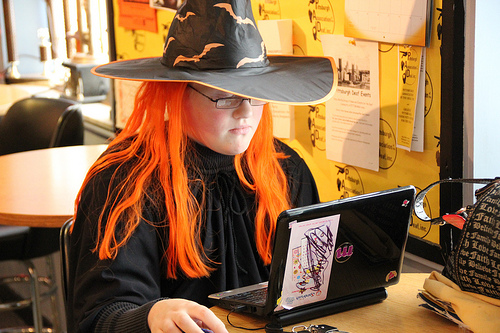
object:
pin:
[348, 40, 356, 46]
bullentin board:
[113, 0, 435, 244]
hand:
[146, 297, 234, 332]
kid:
[70, 0, 343, 333]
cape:
[85, 164, 295, 224]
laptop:
[209, 186, 424, 326]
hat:
[90, 0, 339, 108]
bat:
[172, 40, 227, 66]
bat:
[235, 41, 271, 68]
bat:
[215, 0, 259, 31]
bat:
[175, 11, 195, 22]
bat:
[163, 36, 175, 54]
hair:
[79, 82, 300, 275]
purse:
[410, 173, 500, 297]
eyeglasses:
[180, 87, 276, 110]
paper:
[343, 0, 432, 47]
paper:
[320, 35, 383, 173]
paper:
[249, 17, 286, 49]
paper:
[396, 46, 423, 154]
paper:
[117, 0, 160, 33]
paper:
[149, 0, 181, 12]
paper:
[112, 78, 167, 130]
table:
[169, 271, 498, 333]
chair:
[0, 95, 86, 155]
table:
[0, 144, 108, 225]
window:
[0, 0, 130, 123]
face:
[196, 85, 274, 155]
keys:
[290, 322, 317, 333]